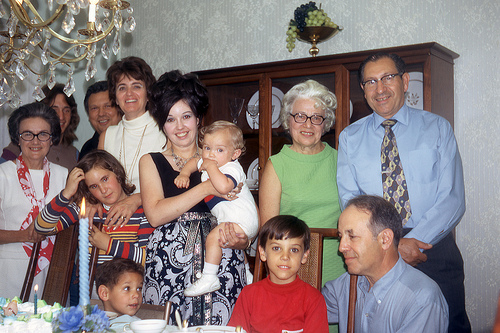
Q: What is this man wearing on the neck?
A: A tie.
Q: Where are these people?
A: In the dining room.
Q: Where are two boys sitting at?
A: At the dining table.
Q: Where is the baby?
A: In the mother's arms.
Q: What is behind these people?
A: Display cabinet.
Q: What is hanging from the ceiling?
A: Chandelier.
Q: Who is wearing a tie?
A: Man standing up.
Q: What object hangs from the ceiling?
A: Chandelier.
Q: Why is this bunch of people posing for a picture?
A: Family picture.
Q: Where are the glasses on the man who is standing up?
A: On his face.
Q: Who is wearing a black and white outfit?
A: Woman with baby.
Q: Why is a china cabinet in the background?
A: Family home.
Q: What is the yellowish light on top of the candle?
A: Fire.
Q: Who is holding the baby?
A: Woman with black and white dress.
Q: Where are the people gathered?
A: Dining room.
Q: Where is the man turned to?
A: Boy.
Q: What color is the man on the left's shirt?
A: Blue.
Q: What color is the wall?
A: White.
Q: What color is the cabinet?
A: Brown.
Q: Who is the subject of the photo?
A: The family.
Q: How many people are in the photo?
A: 12.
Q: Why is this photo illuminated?
A: Light fixtures.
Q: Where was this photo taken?
A: A dining room.